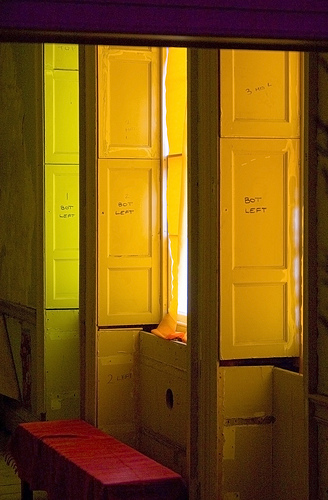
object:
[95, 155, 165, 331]
cabinet panel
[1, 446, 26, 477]
fringe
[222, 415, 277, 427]
holes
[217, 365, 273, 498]
board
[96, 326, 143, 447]
board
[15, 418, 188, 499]
bench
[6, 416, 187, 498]
blanket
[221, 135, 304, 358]
door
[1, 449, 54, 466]
floor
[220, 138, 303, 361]
white panel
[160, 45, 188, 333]
window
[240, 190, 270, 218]
words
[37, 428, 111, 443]
crease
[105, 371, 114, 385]
number 2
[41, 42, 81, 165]
doors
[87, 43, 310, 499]
different colors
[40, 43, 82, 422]
different colors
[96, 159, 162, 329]
shutter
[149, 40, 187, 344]
material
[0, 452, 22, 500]
boards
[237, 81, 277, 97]
writing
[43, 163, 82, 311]
cabinet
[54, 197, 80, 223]
word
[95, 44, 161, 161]
doors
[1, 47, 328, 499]
wall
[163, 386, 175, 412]
hole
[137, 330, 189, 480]
wood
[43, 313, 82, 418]
paint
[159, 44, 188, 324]
light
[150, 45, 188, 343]
drapes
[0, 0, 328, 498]
room